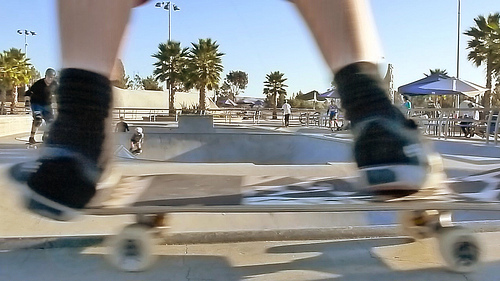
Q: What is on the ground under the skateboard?
A: A shadow.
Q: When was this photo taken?
A: Daytime.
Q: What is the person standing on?
A: A skateboard.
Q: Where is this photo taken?
A: At a skatepark.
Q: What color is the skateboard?
A: Black and white.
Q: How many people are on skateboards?
A: Three.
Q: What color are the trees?
A: Green.